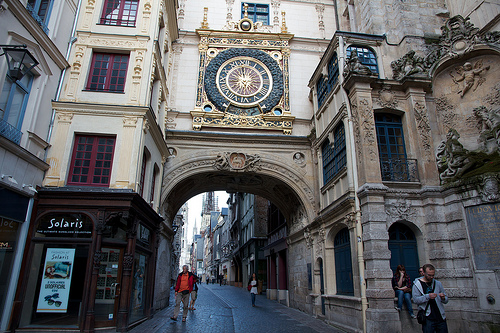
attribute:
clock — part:
[206, 41, 287, 115]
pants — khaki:
[164, 290, 192, 321]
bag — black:
[403, 303, 435, 327]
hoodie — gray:
[410, 277, 447, 319]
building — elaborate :
[149, 37, 491, 247]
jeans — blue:
[248, 292, 258, 307]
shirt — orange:
[179, 273, 189, 292]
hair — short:
[423, 266, 435, 267]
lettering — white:
[35, 211, 106, 243]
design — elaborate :
[390, 6, 498, 184]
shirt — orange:
[174, 272, 194, 296]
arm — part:
[195, 270, 205, 285]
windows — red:
[70, 117, 125, 198]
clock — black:
[218, 54, 276, 105]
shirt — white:
[244, 278, 256, 300]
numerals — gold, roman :
[217, 55, 271, 102]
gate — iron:
[384, 160, 414, 183]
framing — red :
[88, 150, 95, 157]